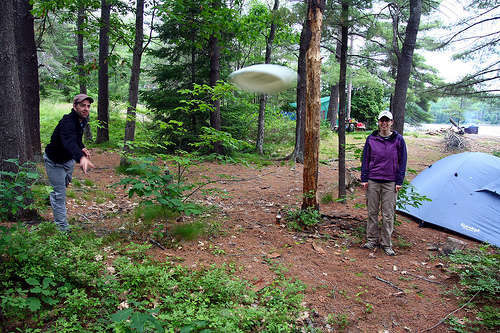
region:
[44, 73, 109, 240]
a man throwing a frisbee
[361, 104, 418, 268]
a woman wearing a purple jacket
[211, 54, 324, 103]
a frisbee flying in the air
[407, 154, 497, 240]
a blue tent in the woods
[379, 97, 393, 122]
a white hat covering a head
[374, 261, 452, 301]
twigs scattered on the ground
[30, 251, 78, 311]
poison ivy growing nearby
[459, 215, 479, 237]
a company logo on a tent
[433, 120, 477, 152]
a pile of tree branches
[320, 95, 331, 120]
a small green shack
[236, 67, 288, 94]
this is a frizbey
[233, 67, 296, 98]
the frizbey is white in color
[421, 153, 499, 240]
this is a tent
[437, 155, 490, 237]
the tent is blue in color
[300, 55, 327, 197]
this is the tree trunk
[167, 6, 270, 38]
these are leaves of a tree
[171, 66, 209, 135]
the leaves are green in color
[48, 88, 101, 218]
this is a person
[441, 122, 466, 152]
this is a dry wood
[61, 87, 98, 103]
this is acap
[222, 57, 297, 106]
A white frisbee being thrown.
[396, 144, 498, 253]
A blue camping tent.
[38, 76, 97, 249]
A man throwing a frisbee.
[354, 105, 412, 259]
A woman smiling.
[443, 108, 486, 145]
A grill cooking food.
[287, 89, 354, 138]
A large green tent.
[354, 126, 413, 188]
A purple coat that is worn by the woman.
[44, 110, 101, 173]
A black coat worn by the man.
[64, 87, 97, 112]
A brown hat being worn by the man.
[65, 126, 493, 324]
A campground site.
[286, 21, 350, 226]
the tree is brown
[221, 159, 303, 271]
the ground is brown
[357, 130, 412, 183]
the shirt is purple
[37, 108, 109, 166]
the shirt is black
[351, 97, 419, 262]
the man is standing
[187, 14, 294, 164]
the tree is green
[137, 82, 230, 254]
the plants are green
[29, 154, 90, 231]
the pants are gray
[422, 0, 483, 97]
the sky is white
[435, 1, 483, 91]
the sky is clear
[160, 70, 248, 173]
the plants are green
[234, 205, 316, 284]
the ground is brown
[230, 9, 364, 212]
the tree is brown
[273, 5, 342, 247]
the tree is tall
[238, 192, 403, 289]
the ground is dirty